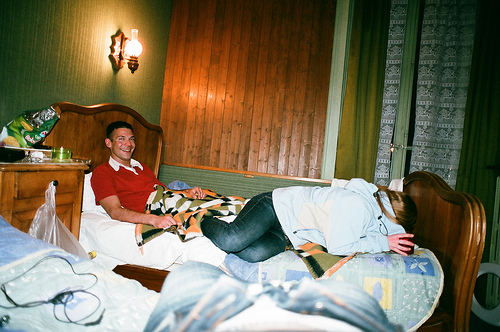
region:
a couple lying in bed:
[86, 120, 421, 283]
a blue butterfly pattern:
[406, 254, 431, 276]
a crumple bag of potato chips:
[11, 106, 63, 142]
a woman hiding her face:
[224, 182, 416, 272]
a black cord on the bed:
[31, 249, 109, 330]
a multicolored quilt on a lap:
[155, 192, 207, 225]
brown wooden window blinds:
[206, 25, 283, 150]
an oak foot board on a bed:
[440, 191, 488, 258]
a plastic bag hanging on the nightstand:
[41, 191, 68, 238]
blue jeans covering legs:
[237, 205, 271, 253]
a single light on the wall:
[84, 12, 194, 104]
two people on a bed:
[69, 100, 449, 260]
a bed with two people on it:
[71, 85, 496, 317]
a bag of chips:
[3, 97, 76, 174]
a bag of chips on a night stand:
[1, 95, 88, 223]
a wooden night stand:
[1, 134, 125, 271]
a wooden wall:
[129, 0, 392, 193]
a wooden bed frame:
[21, 89, 485, 326]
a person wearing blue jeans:
[209, 154, 411, 280]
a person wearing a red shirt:
[23, 80, 188, 230]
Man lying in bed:
[91, 121, 206, 245]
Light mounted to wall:
[105, 23, 146, 88]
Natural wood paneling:
[192, 15, 299, 160]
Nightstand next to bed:
[0, 161, 90, 246]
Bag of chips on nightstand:
[0, 96, 67, 164]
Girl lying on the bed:
[192, 178, 422, 266]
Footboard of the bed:
[400, 166, 482, 331]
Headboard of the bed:
[42, 101, 173, 183]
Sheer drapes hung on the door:
[415, 3, 462, 232]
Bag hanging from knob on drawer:
[27, 175, 90, 270]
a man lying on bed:
[93, 121, 239, 235]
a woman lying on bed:
[193, 170, 412, 268]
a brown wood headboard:
[44, 104, 163, 191]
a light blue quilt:
[222, 228, 433, 324]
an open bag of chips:
[0, 105, 60, 147]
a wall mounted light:
[103, 23, 143, 78]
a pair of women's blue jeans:
[193, 189, 286, 261]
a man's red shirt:
[88, 158, 165, 214]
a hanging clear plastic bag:
[29, 176, 83, 258]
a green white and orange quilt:
[143, 176, 348, 277]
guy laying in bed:
[84, 118, 229, 248]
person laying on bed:
[189, 185, 421, 273]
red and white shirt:
[89, 141, 199, 227]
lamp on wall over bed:
[58, 7, 164, 176]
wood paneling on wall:
[161, 55, 354, 215]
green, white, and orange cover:
[142, 179, 234, 246]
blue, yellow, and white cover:
[357, 264, 465, 330]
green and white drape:
[379, 17, 474, 204]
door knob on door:
[369, 130, 422, 170]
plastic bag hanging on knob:
[7, 159, 132, 293]